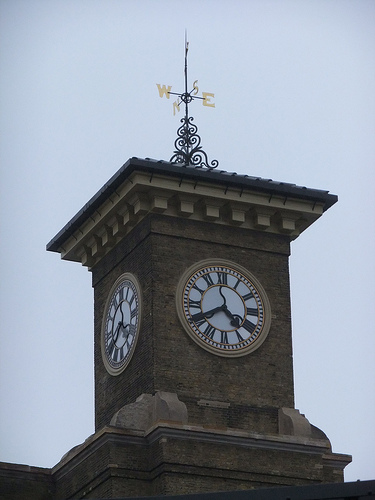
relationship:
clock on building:
[177, 256, 275, 359] [0, 157, 374, 499]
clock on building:
[101, 273, 142, 376] [0, 157, 374, 499]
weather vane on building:
[157, 30, 220, 168] [0, 157, 374, 499]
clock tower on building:
[45, 156, 339, 448] [0, 157, 374, 499]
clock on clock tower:
[177, 256, 275, 359] [45, 156, 339, 448]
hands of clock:
[189, 306, 240, 327] [177, 256, 275, 359]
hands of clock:
[107, 323, 127, 352] [101, 273, 142, 376]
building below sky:
[0, 157, 374, 499] [2, 0, 373, 482]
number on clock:
[216, 271, 227, 288] [177, 256, 275, 359]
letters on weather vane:
[156, 80, 214, 114] [157, 30, 220, 168]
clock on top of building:
[177, 256, 275, 359] [0, 157, 374, 499]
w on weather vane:
[157, 82, 172, 99] [157, 30, 220, 168]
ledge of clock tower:
[51, 423, 352, 484] [45, 156, 339, 448]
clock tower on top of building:
[45, 156, 339, 448] [0, 157, 374, 499]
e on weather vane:
[201, 91, 213, 109] [157, 30, 220, 168]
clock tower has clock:
[45, 156, 339, 448] [175, 256, 273, 359]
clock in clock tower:
[177, 256, 275, 359] [45, 156, 339, 448]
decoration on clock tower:
[48, 154, 336, 265] [45, 156, 339, 448]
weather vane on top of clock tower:
[157, 30, 220, 168] [45, 156, 339, 448]